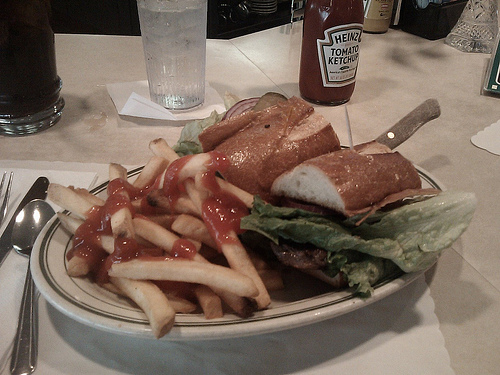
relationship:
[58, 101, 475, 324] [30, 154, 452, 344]
food on a plate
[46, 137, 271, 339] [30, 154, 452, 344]
french fries on a plate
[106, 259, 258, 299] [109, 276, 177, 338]
french fry with french fry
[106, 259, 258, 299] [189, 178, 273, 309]
french fry with french fry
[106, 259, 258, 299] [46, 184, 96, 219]
french fry with french fry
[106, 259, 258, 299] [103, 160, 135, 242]
french fry with french fry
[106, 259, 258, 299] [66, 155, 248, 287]
french fry with ketchup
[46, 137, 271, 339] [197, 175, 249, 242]
french fries with ketchup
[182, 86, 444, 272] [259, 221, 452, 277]
sandwich with lettuce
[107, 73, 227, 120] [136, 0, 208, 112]
napkin under a glass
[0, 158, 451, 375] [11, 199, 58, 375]
placemat under silver spoon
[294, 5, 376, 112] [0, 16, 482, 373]
ketchup on table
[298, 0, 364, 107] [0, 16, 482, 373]
ketchup on table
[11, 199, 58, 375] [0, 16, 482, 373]
silver spoon on table